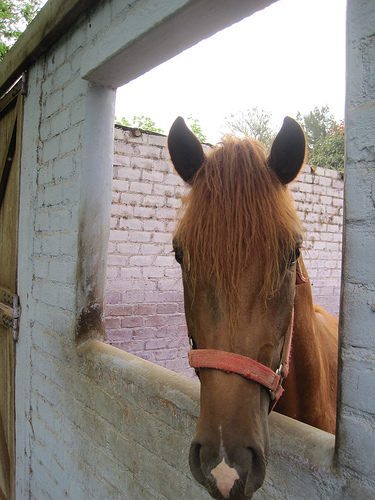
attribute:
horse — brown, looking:
[152, 104, 356, 498]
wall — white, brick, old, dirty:
[23, 6, 372, 500]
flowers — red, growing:
[323, 122, 344, 143]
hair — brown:
[182, 128, 297, 306]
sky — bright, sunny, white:
[4, 4, 348, 169]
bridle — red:
[178, 295, 306, 404]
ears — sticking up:
[163, 113, 308, 182]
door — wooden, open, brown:
[1, 69, 45, 500]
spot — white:
[208, 441, 242, 500]